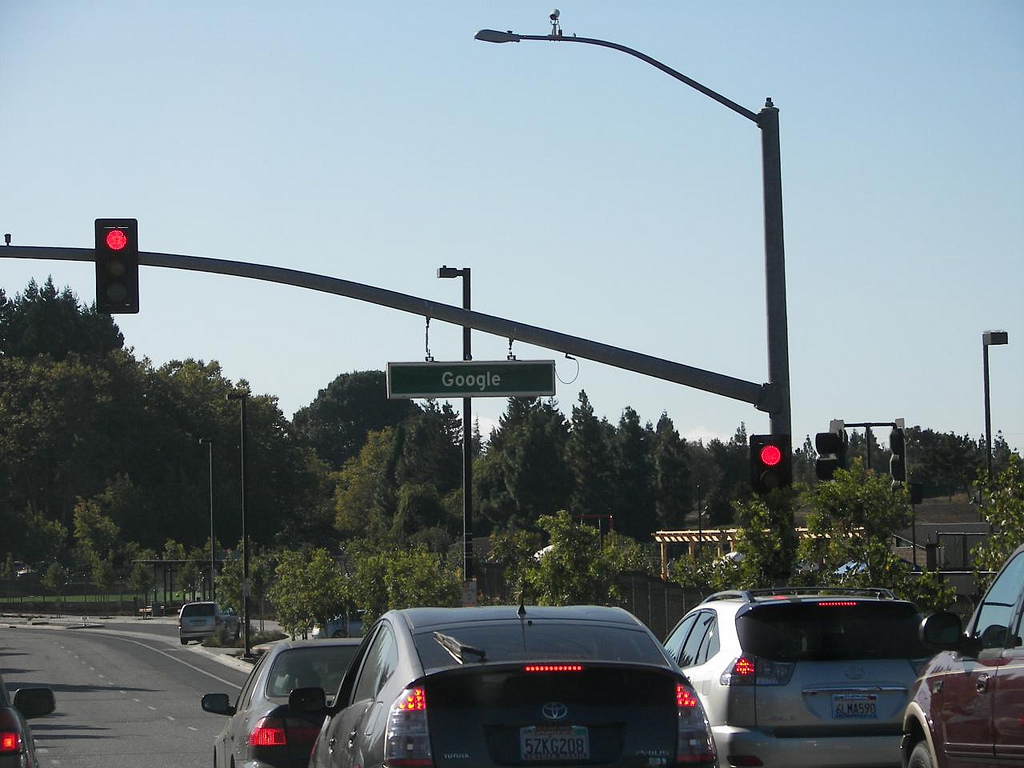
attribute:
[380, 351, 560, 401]
street sign — green and white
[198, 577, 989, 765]
group — cars